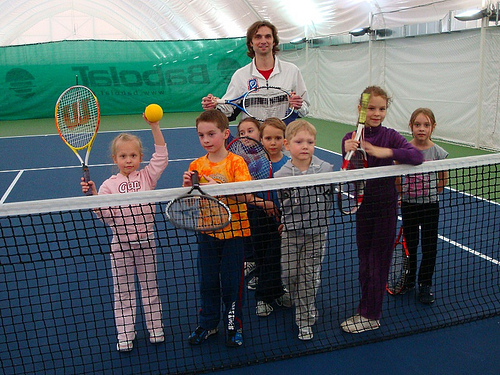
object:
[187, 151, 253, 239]
shirt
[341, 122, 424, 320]
track suit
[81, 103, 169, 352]
child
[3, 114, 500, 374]
court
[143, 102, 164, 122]
ball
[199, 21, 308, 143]
coach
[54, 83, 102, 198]
racket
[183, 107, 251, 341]
boy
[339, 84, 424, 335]
girl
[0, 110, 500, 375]
court.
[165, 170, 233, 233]
racket.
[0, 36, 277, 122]
tent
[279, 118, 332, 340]
boy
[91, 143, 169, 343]
suit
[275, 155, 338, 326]
suit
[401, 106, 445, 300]
girl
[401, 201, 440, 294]
pants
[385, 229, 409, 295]
racket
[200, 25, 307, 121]
man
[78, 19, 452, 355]
group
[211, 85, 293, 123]
racket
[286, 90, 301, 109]
hands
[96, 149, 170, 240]
sweater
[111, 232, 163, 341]
pants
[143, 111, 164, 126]
hand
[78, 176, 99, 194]
hand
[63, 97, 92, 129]
letter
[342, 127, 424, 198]
shirt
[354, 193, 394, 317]
pants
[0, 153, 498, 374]
net